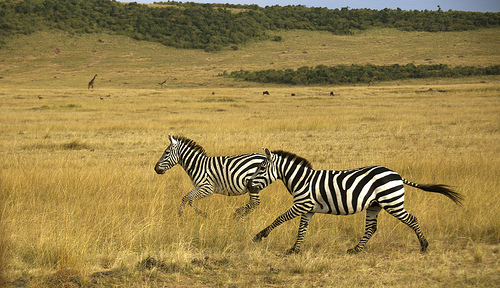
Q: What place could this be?
A: It is a field.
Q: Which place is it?
A: It is a field.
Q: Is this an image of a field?
A: Yes, it is showing a field.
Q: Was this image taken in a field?
A: Yes, it was taken in a field.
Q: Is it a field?
A: Yes, it is a field.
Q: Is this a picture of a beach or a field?
A: It is showing a field.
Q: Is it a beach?
A: No, it is a field.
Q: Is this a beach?
A: No, it is a field.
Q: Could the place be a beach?
A: No, it is a field.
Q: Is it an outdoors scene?
A: Yes, it is outdoors.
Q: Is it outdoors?
A: Yes, it is outdoors.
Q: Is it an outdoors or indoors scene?
A: It is outdoors.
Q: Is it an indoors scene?
A: No, it is outdoors.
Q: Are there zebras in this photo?
A: Yes, there are zebras.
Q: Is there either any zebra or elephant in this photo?
A: Yes, there are zebras.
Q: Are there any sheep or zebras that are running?
A: Yes, the zebras are running.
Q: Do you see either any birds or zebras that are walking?
A: Yes, the zebras are walking.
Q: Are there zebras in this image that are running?
A: Yes, there are zebras that are running.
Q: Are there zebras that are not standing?
A: Yes, there are zebras that are running.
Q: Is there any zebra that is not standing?
A: Yes, there are zebras that are running.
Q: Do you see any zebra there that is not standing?
A: Yes, there are zebras that are running .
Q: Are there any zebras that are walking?
A: Yes, there are zebras that are walking.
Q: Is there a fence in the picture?
A: No, there are no fences.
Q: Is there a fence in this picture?
A: No, there are no fences.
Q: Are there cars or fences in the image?
A: No, there are no fences or cars.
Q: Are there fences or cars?
A: No, there are no fences or cars.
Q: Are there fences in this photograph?
A: No, there are no fences.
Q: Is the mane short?
A: Yes, the mane is short.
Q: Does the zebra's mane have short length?
A: Yes, the mane is short.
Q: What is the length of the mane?
A: The mane is short.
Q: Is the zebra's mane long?
A: No, the mane is short.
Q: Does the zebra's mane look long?
A: No, the mane is short.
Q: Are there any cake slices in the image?
A: No, there are no cake slices.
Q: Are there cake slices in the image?
A: No, there are no cake slices.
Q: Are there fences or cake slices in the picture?
A: No, there are no cake slices or fences.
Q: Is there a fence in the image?
A: No, there are no fences.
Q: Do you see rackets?
A: No, there are no rackets.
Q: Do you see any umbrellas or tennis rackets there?
A: No, there are no tennis rackets or umbrellas.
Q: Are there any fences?
A: No, there are no fences.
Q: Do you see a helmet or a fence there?
A: No, there are no fences or helmets.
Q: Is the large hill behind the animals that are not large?
A: Yes, the hill is behind the animals.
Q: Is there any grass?
A: Yes, there is grass.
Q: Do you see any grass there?
A: Yes, there is grass.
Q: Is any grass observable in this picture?
A: Yes, there is grass.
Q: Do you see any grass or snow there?
A: Yes, there is grass.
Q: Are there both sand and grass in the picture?
A: No, there is grass but no sand.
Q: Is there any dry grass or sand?
A: Yes, there is dry grass.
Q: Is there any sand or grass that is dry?
A: Yes, the grass is dry.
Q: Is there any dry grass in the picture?
A: Yes, there is dry grass.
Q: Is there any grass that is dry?
A: Yes, there is grass that is dry.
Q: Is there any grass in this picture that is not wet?
A: Yes, there is dry grass.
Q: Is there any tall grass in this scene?
A: Yes, there is tall grass.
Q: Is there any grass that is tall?
A: Yes, there is grass that is tall.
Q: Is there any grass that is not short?
A: Yes, there is tall grass.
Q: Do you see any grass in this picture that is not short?
A: Yes, there is tall grass.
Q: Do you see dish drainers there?
A: No, there are no dish drainers.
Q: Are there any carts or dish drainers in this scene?
A: No, there are no dish drainers or carts.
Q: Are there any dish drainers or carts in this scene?
A: No, there are no dish drainers or carts.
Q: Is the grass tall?
A: Yes, the grass is tall.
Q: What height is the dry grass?
A: The grass is tall.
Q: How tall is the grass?
A: The grass is tall.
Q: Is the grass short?
A: No, the grass is tall.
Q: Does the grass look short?
A: No, the grass is tall.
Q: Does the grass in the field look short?
A: No, the grass is tall.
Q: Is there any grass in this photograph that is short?
A: No, there is grass but it is tall.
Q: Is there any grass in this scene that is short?
A: No, there is grass but it is tall.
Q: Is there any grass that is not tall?
A: No, there is grass but it is tall.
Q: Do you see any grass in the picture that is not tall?
A: No, there is grass but it is tall.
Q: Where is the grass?
A: The grass is in the field.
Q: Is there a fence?
A: No, there are no fences.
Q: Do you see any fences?
A: No, there are no fences.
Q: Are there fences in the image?
A: No, there are no fences.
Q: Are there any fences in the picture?
A: No, there are no fences.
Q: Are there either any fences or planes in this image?
A: No, there are no fences or planes.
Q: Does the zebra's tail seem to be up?
A: Yes, the tail is up.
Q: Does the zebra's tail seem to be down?
A: No, the tail is up.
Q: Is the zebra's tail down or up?
A: The tail is up.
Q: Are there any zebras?
A: Yes, there is a zebra.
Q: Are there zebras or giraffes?
A: Yes, there is a zebra.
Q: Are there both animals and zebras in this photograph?
A: Yes, there are both a zebra and an animal.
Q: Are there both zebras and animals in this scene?
A: Yes, there are both a zebra and an animal.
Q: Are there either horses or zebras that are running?
A: Yes, the zebra is running.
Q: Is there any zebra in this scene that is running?
A: Yes, there is a zebra that is running.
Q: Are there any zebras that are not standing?
A: Yes, there is a zebra that is running.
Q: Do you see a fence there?
A: No, there are no fences.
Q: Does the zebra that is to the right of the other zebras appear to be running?
A: Yes, the zebra is running.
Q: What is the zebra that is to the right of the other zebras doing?
A: The zebra is running.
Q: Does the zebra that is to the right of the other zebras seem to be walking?
A: No, the zebra is running.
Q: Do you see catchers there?
A: No, there are no catchers.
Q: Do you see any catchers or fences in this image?
A: No, there are no catchers or fences.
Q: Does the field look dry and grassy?
A: Yes, the field is dry and grassy.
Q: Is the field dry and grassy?
A: Yes, the field is dry and grassy.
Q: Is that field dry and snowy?
A: No, the field is dry but grassy.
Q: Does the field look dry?
A: Yes, the field is dry.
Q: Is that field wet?
A: No, the field is dry.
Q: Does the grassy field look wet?
A: No, the field is dry.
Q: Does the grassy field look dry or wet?
A: The field is dry.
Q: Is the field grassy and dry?
A: Yes, the field is grassy and dry.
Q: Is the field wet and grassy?
A: No, the field is grassy but dry.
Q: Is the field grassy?
A: Yes, the field is grassy.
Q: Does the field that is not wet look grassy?
A: Yes, the field is grassy.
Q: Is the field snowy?
A: No, the field is grassy.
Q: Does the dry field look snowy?
A: No, the field is grassy.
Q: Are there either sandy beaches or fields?
A: No, there is a field but it is grassy.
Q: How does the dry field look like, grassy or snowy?
A: The field is grassy.